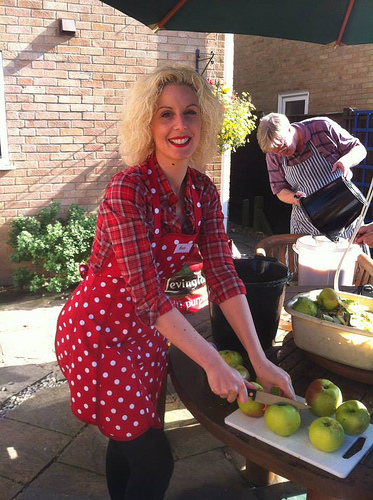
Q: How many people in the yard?
A: Two.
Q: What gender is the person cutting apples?
A: Female.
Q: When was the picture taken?
A: Daytime.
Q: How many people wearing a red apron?
A: One.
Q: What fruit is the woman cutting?
A: Apple.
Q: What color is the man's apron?
A: Black and white.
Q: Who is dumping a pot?
A: A man.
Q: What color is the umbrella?
A: Green.